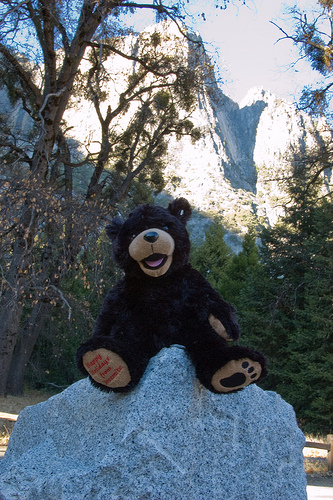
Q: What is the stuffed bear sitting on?
A: A rock.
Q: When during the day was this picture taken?
A: Daytime.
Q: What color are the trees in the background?
A: Green.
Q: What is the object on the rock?
A: A teddy bear.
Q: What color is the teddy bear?
A: Brown and tan.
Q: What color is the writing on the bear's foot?
A: Red.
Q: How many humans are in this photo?
A: None.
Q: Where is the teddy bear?
A: On top of the rock.